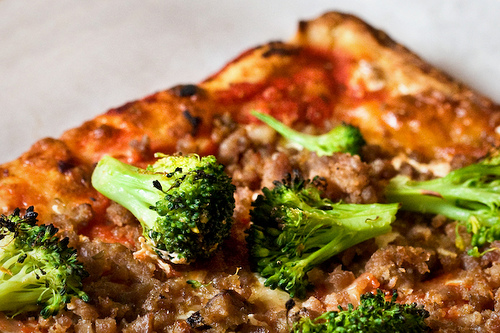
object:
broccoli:
[87, 150, 235, 264]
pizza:
[1, 11, 500, 332]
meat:
[220, 127, 383, 212]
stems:
[91, 153, 158, 207]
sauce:
[247, 46, 366, 131]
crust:
[304, 1, 499, 130]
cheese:
[355, 99, 491, 149]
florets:
[186, 161, 236, 202]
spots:
[167, 83, 204, 98]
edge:
[307, 1, 498, 112]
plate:
[1, 2, 500, 160]